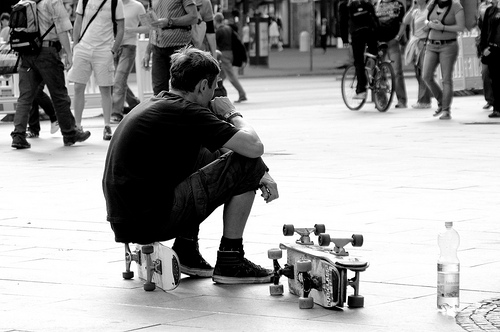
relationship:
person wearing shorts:
[62, 0, 126, 141] [68, 36, 127, 95]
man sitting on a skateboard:
[102, 45, 278, 282] [120, 240, 181, 292]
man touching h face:
[102, 45, 278, 288] [185, 62, 236, 132]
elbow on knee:
[245, 136, 265, 157] [230, 146, 265, 183]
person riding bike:
[337, 0, 385, 95] [341, 40, 398, 112]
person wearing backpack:
[6, 0, 90, 149] [4, 0, 56, 57]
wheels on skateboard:
[281, 219, 366, 249] [276, 219, 372, 265]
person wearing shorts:
[60, 0, 127, 142] [64, 50, 119, 90]